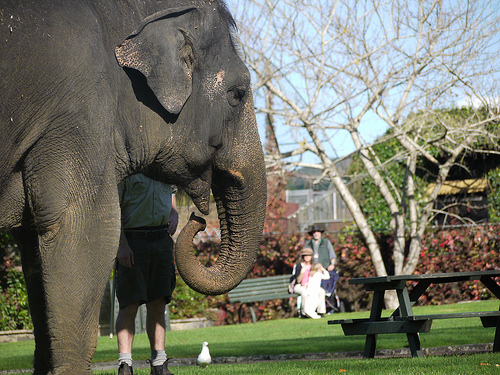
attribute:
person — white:
[290, 246, 330, 321]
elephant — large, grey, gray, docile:
[1, 1, 270, 374]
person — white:
[297, 224, 341, 314]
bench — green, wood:
[224, 270, 338, 324]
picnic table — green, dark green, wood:
[327, 264, 499, 361]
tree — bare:
[205, 0, 499, 316]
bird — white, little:
[195, 339, 214, 370]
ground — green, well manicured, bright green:
[1, 300, 500, 374]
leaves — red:
[193, 220, 497, 327]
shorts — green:
[113, 223, 179, 309]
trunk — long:
[173, 161, 267, 299]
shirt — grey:
[113, 169, 179, 232]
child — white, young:
[308, 263, 331, 300]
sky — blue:
[216, 1, 499, 180]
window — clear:
[430, 194, 491, 226]